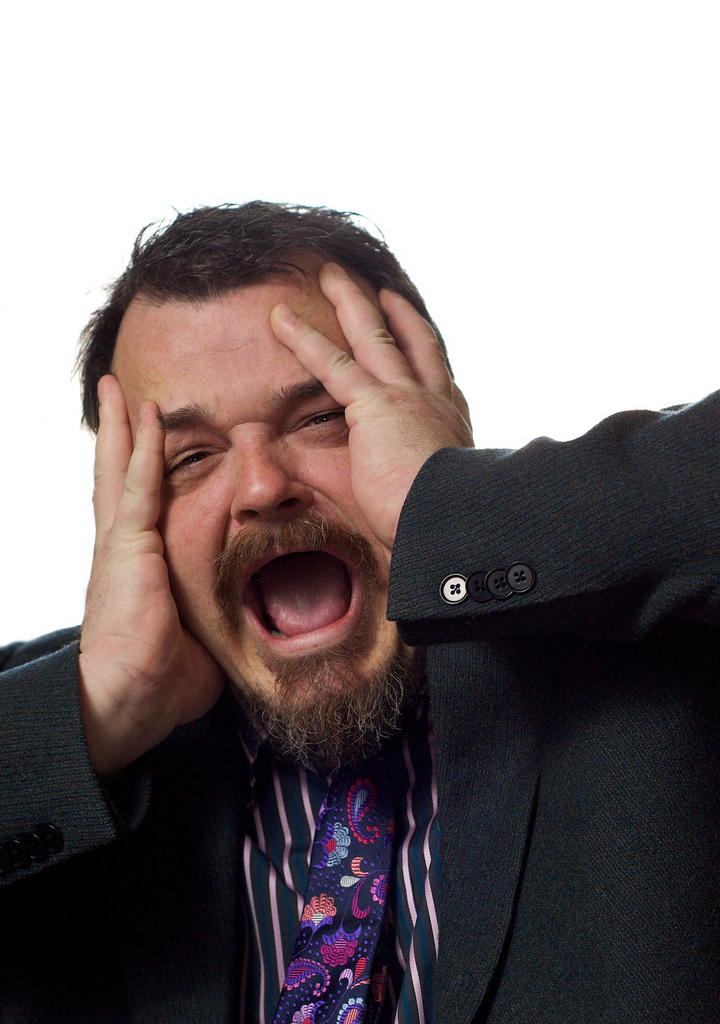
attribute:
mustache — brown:
[211, 508, 373, 572]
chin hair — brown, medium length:
[229, 638, 425, 791]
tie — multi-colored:
[268, 785, 442, 1007]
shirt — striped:
[55, 655, 688, 973]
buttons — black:
[416, 557, 527, 606]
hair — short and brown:
[85, 178, 327, 336]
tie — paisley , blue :
[270, 751, 398, 1021]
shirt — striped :
[236, 702, 444, 1017]